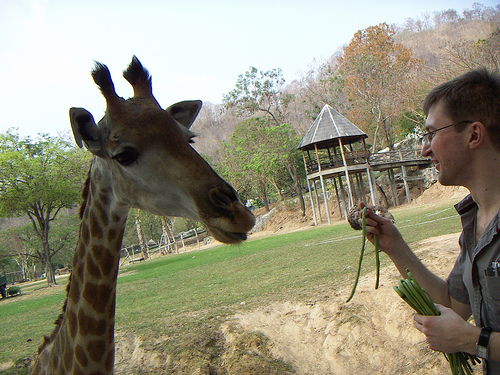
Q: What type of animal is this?
A: Giraffe.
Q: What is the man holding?
A: Plants.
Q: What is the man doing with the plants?
A: Feeding the giraffe.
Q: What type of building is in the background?
A: Observatory.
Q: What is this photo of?
A: A zoo.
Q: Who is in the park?
A: A man.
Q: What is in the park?
A: A giraffe.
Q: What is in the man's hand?
A: Food.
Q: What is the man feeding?
A: A giraffe.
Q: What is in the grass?
A: A gazebo.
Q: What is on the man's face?
A: Glasses.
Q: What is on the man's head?
A: Black hair.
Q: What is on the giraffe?
A: Spots.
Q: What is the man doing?
A: Feeding the giraffe.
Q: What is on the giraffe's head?
A: Horns.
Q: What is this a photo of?
A: A man feeding a giraffe.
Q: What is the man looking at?
A: A giraffe.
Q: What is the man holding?
A: Green vegetation.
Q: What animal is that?
A: Giraffe.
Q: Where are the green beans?
A: In the guys hand.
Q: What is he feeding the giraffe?
A: Green beans.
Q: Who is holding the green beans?
A: The man.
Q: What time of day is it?
A: Daytime.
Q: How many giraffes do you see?
A: One.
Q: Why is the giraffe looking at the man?
A: He wants the green beans.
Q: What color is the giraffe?
A: Brown.